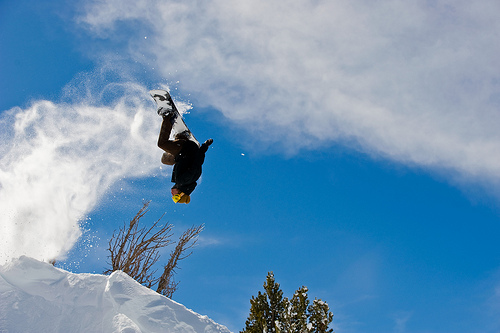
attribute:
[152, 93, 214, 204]
person — flipping, snowboarder, upside down, snowboarding, doing trick, doing tricks, alone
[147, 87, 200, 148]
snowboard — snowy, black, white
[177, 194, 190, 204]
hat — yellow, knit, brown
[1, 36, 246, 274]
snow — flying, white, powdery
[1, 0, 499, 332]
air — clear, blue, sky, bright blue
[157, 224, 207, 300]
weed — dead, barren, brown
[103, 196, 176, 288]
weed — dead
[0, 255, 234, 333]
snowbank — ridge, snow covered, mounded, white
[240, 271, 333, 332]
tree — snowy, leafy, green, top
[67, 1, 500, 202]
cloud — grey, big, white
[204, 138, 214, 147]
glove — black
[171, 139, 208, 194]
jacket — dark, black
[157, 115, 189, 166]
pants — brown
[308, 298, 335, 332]
branch — snowy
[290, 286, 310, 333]
branch — snowy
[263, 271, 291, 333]
branch — snowy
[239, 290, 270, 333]
branch — snowy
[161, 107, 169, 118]
snow — white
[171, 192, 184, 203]
goggles — yellow